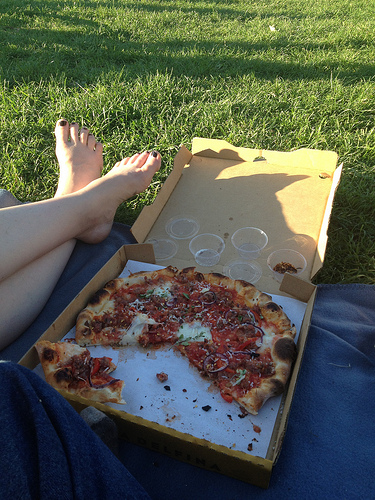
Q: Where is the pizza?
A: In the box.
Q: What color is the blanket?
A: Blue.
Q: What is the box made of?
A: Cardboard.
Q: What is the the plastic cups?
A: Crushed red peppers.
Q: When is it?
A: Day time.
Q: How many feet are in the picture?
A: Two.